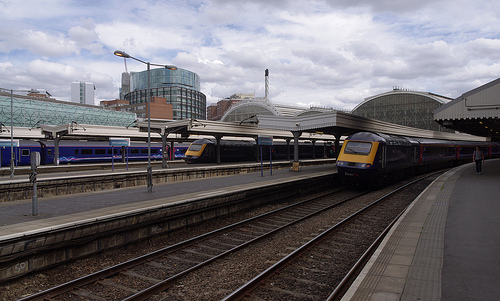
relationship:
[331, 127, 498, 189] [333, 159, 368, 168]
train has headlight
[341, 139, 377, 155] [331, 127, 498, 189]
windshield on train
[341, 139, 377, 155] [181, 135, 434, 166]
windshield on train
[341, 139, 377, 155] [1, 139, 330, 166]
windshield on train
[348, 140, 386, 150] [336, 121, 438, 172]
wiper on windshield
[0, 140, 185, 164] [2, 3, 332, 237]
blue train on background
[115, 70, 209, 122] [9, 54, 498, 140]
glass building on background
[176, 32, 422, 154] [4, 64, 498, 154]
building on background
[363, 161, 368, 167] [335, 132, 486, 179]
light on train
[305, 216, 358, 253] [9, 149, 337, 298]
gravel under tracks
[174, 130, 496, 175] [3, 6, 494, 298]
trains in photo